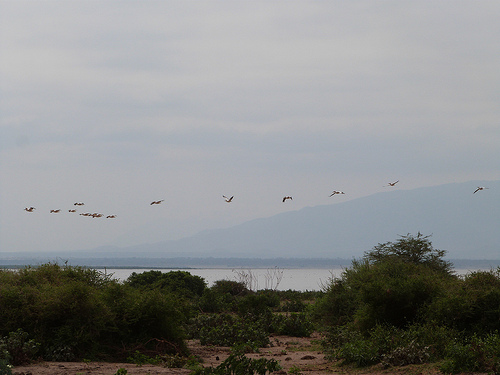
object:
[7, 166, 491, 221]
birds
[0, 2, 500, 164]
sky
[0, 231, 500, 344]
bush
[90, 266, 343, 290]
water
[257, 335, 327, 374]
sand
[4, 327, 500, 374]
dirt